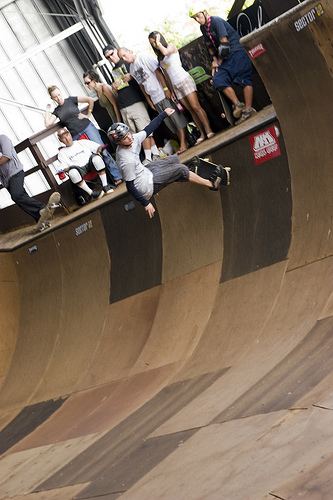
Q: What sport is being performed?
A: Skateboarding.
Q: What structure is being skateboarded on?
A: A ramp.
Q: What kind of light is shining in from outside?
A: Sunlight.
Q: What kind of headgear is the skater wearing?
A: A helmet.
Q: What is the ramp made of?
A: Wood.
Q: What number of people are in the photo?
A: Nine.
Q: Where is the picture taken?
A: A skate park.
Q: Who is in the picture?
A: Men and women.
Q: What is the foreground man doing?
A: Skateboarding.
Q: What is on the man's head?
A: A helmet.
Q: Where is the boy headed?
A: Down.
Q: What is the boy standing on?
A: A skateboard.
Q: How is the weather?
A: Clear.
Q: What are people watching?
A: The boy.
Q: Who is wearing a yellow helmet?
A: A man.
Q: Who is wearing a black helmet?
A: The skateboarder.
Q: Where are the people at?
A: A skate park.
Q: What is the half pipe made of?
A: Wood.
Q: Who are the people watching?
A: Spectators.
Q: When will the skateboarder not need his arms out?
A: When he is done with his trick.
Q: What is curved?
A: A skating ramp.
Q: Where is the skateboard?
A: Under the skateboarder's feet.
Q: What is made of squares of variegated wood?
A: The ramp.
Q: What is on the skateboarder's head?
A: A helmet.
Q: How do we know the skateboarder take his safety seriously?
A: He is wearing a helmet.